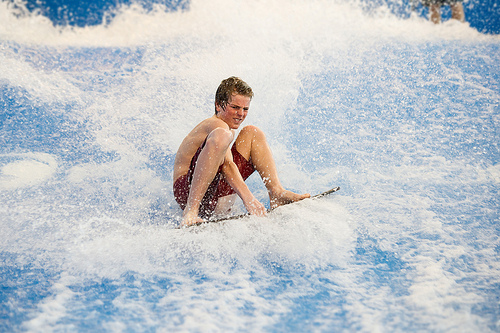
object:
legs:
[447, 1, 467, 24]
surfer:
[171, 75, 316, 230]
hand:
[243, 196, 268, 218]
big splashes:
[325, 33, 374, 102]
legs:
[428, 0, 444, 25]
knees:
[244, 126, 265, 138]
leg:
[180, 126, 234, 227]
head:
[215, 77, 252, 131]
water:
[1, 0, 500, 333]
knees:
[211, 125, 231, 149]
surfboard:
[130, 173, 357, 236]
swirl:
[2, 117, 87, 219]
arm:
[216, 119, 254, 204]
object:
[424, 0, 466, 28]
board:
[169, 186, 342, 231]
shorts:
[173, 142, 253, 217]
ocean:
[0, 0, 499, 333]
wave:
[57, 222, 362, 276]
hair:
[213, 75, 253, 114]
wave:
[0, 7, 175, 274]